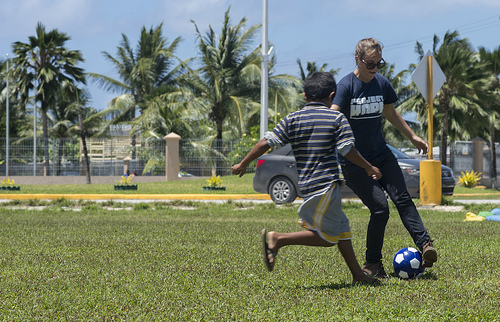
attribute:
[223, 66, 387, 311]
boy — young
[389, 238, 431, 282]
ball — blue, white, rolling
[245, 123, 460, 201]
car — gray, parked, silver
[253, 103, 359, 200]
shirt — striped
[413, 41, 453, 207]
post — yellow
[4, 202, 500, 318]
field — green, grass, grassy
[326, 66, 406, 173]
shirt — navy blue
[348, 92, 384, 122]
writing — white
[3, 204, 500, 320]
grass — green, cut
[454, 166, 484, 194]
flowers — yellow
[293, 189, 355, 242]
trim — yellow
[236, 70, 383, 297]
person — running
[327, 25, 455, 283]
person — running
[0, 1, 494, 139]
sky — blue, clear